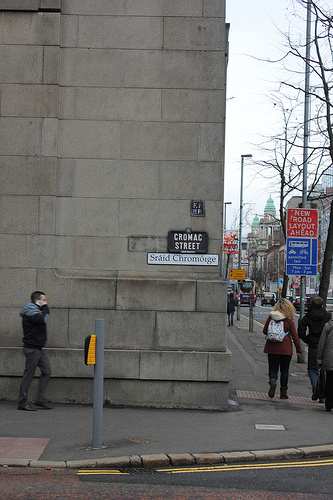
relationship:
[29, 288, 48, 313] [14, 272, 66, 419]
head of person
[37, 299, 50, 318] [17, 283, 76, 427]
arm of person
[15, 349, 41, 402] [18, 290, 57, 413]
leg of person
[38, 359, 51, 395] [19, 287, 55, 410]
leg of person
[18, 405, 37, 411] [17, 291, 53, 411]
feet of man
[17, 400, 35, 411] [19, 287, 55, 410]
feet of person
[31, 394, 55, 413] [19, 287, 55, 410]
feet of person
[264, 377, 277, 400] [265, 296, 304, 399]
feet of person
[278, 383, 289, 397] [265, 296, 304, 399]
feet of person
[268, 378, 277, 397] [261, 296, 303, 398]
feet of person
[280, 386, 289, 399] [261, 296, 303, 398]
feet of person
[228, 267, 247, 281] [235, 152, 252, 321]
sign on pole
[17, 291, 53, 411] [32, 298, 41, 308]
man on phone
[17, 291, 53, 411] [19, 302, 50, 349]
man wearing hoodie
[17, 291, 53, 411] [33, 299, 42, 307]
man holding phone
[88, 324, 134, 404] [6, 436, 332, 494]
pole in street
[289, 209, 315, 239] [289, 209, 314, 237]
letters on letters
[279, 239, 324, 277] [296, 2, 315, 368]
sign on pole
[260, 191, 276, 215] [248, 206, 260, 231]
blue building top of blue building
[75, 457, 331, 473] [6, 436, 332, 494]
lines on side of street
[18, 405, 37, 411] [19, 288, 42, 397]
feet of a person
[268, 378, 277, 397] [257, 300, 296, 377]
feet of a person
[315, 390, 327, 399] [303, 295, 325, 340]
feet of a person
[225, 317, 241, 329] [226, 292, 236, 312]
feet of a person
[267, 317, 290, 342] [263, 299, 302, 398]
backpack on woman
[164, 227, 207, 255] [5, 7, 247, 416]
street sign on building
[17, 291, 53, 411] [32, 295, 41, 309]
man walking with phone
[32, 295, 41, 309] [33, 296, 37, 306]
phone pressed against ear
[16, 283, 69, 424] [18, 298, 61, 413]
man wearing clothing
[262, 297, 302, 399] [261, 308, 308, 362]
person wearing coat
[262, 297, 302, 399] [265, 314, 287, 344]
person wearing a backpack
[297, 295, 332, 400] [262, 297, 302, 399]
man walking together with person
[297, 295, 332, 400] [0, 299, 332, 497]
man walking on street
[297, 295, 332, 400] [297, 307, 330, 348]
man in coat